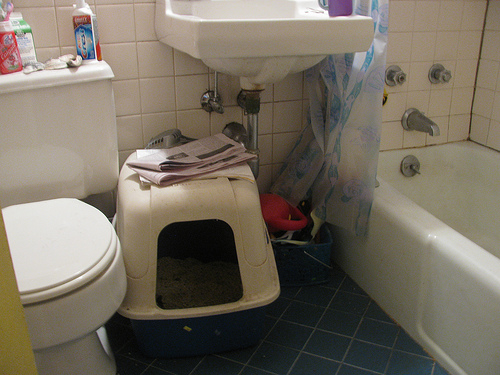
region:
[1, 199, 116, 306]
the toilet seat is down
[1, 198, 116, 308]
the toilet seat is white in color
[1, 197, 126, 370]
the toilet bowl is white in color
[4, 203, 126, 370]
the toilet bowl is made of ceramic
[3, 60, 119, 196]
the tank is white in color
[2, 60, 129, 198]
the tank is made of ceramic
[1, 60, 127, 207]
the tank is against the wall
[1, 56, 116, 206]
the tank is shiny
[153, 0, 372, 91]
the sink is white in color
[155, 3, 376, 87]
the sink is attached to the wall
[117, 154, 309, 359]
a box of kitty liter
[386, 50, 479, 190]
silver plumbing fixtures on tub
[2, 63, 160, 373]
a white toilet seat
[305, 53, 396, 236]
a blue and white shower curtain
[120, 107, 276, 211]
newspaper on top of litter box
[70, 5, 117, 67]
Crest tooth paste on back of toilet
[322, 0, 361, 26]
purple cup on the sink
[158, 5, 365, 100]
a white bathroom sink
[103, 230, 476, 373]
blue tile on the floor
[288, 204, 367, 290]
blue bucket on the floor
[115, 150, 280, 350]
cat litter box under the sink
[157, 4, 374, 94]
a white sink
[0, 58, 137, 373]
a white toilet on the left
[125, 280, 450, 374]
a blue tile bathroom floor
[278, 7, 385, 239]
a plastic shower curtain with light blue pattern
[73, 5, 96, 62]
tube of toothpaste on the toilet tank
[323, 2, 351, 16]
purple cup on lip o sink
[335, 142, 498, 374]
white bathtub on the right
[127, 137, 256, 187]
newspapers on the litter box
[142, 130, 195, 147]
gray plastic litter scooper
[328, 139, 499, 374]
White bathtub in bathroom.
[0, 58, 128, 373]
White flush toilet in bathroom.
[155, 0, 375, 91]
White hand sink in bathroom.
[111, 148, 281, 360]
Plastic litterbox for cats in bathroom.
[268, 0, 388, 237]
Blue and opaque shower curtain.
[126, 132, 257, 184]
Newspapers on a litter box in a bathroom.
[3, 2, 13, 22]
Pink toothbrush in a bathroom.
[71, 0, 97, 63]
Container of Crest toothpaste on a toilet.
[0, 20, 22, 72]
Red and white container holding toothbrushes.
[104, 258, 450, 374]
Blue tiled floor in a bathroom.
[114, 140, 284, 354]
Covered litter box in the bathroom.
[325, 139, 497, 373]
White tub in the bathroom.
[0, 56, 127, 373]
white toilet in the bathroom.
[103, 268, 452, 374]
Blue tile on the floor.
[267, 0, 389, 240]
Clear and blue shower curtain.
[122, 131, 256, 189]
Newspaper on the litter box.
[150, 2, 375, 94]
White sink in the bathroom.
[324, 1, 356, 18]
Purple cup on the sink.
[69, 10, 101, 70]
toothpaste box on the toilet.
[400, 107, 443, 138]
Silver faucet on the wall.